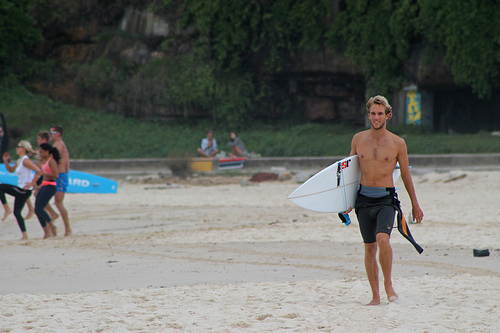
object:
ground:
[319, 168, 351, 196]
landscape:
[0, 0, 499, 158]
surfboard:
[1, 162, 119, 194]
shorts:
[55, 171, 69, 194]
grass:
[73, 111, 133, 156]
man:
[342, 94, 424, 305]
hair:
[385, 105, 392, 115]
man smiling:
[370, 103, 385, 129]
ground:
[320, 196, 335, 207]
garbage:
[471, 247, 489, 256]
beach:
[0, 167, 499, 331]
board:
[286, 154, 413, 213]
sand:
[193, 290, 250, 320]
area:
[183, 156, 296, 174]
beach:
[170, 266, 486, 330]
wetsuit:
[353, 183, 425, 254]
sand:
[288, 295, 297, 302]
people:
[197, 129, 220, 158]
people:
[225, 131, 249, 158]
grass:
[122, 128, 169, 157]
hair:
[364, 95, 387, 104]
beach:
[4, 250, 170, 331]